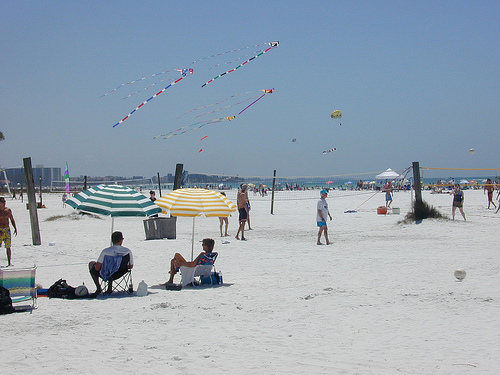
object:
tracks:
[302, 291, 333, 300]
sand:
[0, 189, 499, 374]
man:
[233, 182, 254, 243]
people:
[86, 230, 133, 298]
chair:
[176, 253, 219, 289]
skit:
[100, 65, 195, 131]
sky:
[364, 5, 492, 135]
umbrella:
[376, 165, 404, 182]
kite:
[100, 39, 280, 97]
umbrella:
[149, 185, 239, 221]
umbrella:
[67, 177, 164, 223]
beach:
[3, 187, 498, 368]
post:
[409, 158, 427, 222]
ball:
[454, 265, 470, 282]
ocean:
[299, 174, 357, 187]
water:
[316, 169, 329, 184]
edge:
[296, 183, 334, 195]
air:
[135, 20, 310, 144]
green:
[63, 181, 164, 220]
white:
[177, 196, 225, 205]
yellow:
[177, 193, 214, 201]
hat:
[317, 186, 330, 195]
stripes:
[155, 185, 235, 222]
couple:
[93, 250, 137, 297]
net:
[419, 167, 499, 205]